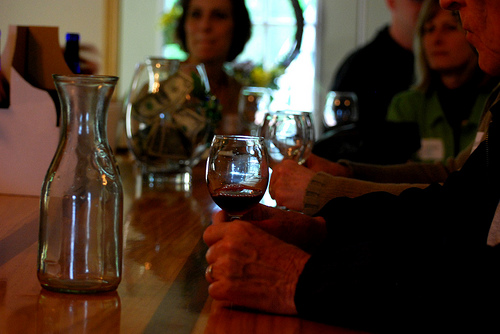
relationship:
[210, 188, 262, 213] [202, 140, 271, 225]
red wine in glass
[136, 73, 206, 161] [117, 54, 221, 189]
bills in dish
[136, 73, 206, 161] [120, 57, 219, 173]
bills are in jar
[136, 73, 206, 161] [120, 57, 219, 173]
bills in jar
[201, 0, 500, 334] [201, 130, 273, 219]
man holding wine glass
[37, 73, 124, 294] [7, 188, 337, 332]
bottle sitting on table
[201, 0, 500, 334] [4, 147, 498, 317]
man sitting at table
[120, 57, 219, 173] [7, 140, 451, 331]
jar on table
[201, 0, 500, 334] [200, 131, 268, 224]
man holding wine glass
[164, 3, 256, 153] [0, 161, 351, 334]
lady sitting at counter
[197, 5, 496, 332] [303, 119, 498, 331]
man wearing shirt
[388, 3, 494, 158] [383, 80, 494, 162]
woman wearing jacket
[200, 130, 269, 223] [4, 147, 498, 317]
glass on table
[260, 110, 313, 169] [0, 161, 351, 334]
glass on counter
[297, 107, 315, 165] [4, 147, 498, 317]
glass on table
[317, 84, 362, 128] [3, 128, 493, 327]
glass on table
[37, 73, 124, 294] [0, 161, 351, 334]
bottle on counter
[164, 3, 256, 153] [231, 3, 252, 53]
lady has hair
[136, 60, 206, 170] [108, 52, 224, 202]
bills are in a bowl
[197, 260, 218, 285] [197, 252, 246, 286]
ring are in man's finger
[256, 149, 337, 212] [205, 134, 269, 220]
hand holding glass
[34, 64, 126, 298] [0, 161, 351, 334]
bottle on a counter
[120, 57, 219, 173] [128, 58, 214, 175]
jar full of money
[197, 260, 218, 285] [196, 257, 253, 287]
ring on man's hand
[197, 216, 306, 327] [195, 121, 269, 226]
hands are on glass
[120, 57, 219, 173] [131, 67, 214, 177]
jar full of money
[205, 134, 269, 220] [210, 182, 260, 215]
glass has red wine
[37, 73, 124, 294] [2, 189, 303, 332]
bottle on counter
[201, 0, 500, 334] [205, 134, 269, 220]
man holding glass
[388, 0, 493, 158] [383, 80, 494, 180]
woman wearing jacket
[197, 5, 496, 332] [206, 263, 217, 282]
man wearing ring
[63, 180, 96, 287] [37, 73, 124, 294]
reflection on bottle